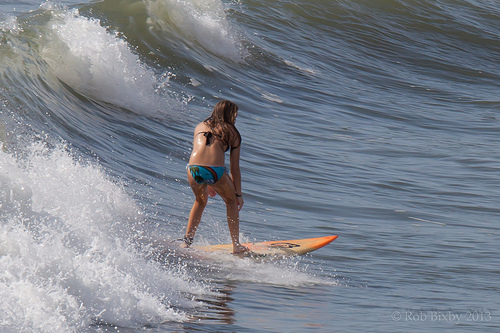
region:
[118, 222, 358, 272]
This is a surfboard.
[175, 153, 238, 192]
These are bikini bottoms.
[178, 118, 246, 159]
This is a bikini top.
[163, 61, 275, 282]
This is a woman.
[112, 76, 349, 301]
This is a woman on a surfboard.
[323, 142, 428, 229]
This is water.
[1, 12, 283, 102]
These are waves.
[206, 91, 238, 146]
This is brown hair.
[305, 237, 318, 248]
This is the color orange.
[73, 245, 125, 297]
This is the color white.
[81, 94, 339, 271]
Woman surfing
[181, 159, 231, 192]
Blue bikini bottom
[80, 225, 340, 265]
Orange surfboard beneath surfer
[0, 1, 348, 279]
Cresting wave behind surfer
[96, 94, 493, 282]
Ocean water ahead of surfer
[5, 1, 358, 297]
Woman surfing in the ocean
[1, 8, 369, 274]
Ocean spray behind surfer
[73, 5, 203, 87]
Green water cresting with spray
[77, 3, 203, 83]
Yellow wave cresting with spray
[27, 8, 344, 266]
Female riding wave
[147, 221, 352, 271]
the surfboard is yellow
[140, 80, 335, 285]
a woman is riding a surfboard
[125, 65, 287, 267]
the woman is wearing a bikini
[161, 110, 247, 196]
the bikini is blue and black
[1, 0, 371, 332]
a woman is riding the wave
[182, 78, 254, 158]
the woman has long, brown hair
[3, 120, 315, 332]
the splashing from the wave is white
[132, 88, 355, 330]
the woman's reflection is in the water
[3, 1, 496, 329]
the water is shiny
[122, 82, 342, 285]
the woman is hunched over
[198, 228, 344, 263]
An orange surf board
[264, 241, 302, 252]
A black design on a surf board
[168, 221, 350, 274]
A surf board in the ocean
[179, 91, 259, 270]
A woman riding a surf board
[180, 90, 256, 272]
A woman in a bikini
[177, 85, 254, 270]
A woman with long hair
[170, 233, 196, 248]
A surf board ankle leash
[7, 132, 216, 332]
The white crest of the waves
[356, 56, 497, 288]
Calm blue water in the foreground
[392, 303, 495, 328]
White watermark copyright in the corner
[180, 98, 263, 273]
lady on surfboard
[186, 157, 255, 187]
Bikini is blue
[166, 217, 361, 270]
Surfboard is orange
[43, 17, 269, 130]
The waves are big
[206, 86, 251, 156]
The lady hair is brown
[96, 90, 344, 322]
Woman is riding with the waves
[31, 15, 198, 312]
The water is choppy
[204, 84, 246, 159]
The lady has long hair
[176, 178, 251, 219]
Knees are ben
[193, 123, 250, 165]
Lady has on bikini top